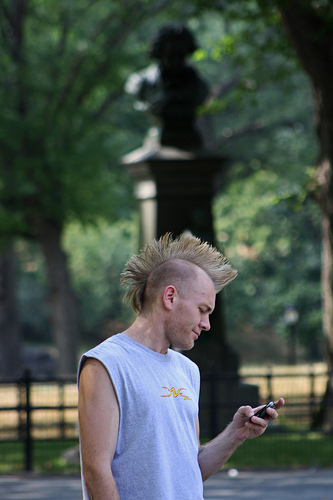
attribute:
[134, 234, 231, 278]
hair — mohawk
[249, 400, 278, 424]
phone — black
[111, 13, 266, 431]
statue — tall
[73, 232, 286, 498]
man — young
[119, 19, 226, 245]
statue — large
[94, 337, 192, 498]
t-shirt — gray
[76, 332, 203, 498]
tank top — gray, yellow, symbol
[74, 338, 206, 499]
shirt — sleeveless, grey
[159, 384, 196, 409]
letters shirt — yellow 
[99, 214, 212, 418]
man — looking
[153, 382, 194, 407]
graphics — yellow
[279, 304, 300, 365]
street lamp — blurry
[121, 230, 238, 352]
head — shaved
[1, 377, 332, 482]
railing — black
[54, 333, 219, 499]
shirt — sleeveless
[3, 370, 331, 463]
fence — black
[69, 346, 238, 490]
shirt — gray